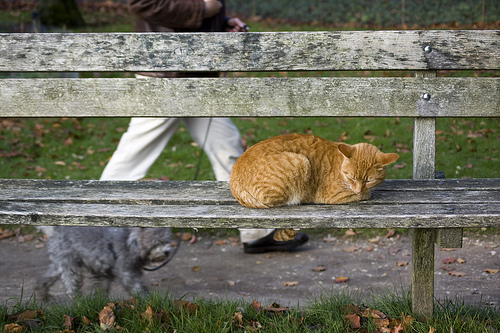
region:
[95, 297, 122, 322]
a dead leaf on the ground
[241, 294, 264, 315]
a dead leaf on the ground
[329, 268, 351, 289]
a dead leaf on the ground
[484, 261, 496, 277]
a dead leaf on the ground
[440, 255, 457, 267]
a dead leaf on the ground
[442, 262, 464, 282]
a dead leaf on the ground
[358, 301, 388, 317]
a dead leaf on the ground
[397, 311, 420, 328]
a dead leaf on the ground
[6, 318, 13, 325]
a dead leaf on the ground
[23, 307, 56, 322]
a dead leaf on the ground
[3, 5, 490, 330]
the cat is sleeping on a bench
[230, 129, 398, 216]
the cat is an orange tabby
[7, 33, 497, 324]
the wooden bench is gray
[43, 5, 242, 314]
a person is walking a dog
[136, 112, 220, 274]
the dog is on a leash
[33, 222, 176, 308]
the dog has silver fur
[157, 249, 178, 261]
the dog has a black nose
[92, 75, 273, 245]
the man is wearing white pants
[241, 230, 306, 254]
the man is wearing dark sandals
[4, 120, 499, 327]
leaves are scattered on the ground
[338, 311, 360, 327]
a dead leaf on the ground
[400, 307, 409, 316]
a dead leaf on the ground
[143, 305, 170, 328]
a dead leaf on the ground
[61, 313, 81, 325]
a dead leaf on the ground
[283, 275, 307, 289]
a dead leaf on the ground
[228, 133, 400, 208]
A tiger cat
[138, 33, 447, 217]
A tiger cat sitting on a bench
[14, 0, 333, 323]
Someone walking a small dog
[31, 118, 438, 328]
Cat suspiciously eyeing a small grey dog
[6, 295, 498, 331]
Un raked leaves on the ground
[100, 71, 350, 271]
Khaki pants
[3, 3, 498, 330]
A park in autumn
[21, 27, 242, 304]
A dog on a leash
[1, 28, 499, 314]
A bench occupied only by a cat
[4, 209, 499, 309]
A sidewalk with leaves and foot traffic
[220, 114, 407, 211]
a orange cat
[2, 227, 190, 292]
a grey dog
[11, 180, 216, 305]
a grey dog being walked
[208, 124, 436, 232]
a orange cat sleeping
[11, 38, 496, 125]
a brown wooden bench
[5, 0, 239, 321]
a person walking a grey dog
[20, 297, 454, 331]
green grass in park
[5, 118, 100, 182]
grass covered in fallen leaves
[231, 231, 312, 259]
black shoes being worn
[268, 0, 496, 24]
green shrubs